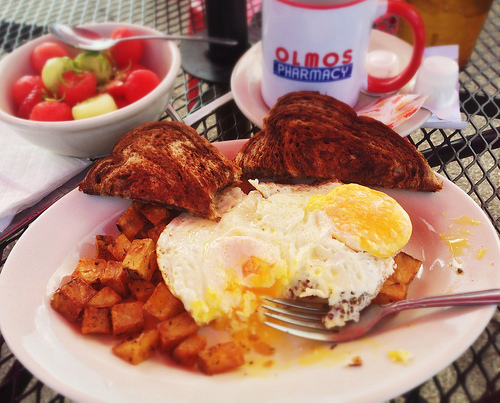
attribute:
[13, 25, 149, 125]
salad — fresh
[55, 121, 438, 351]
breakfast — toast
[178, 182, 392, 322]
eggs — sunny side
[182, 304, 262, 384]
potatoes — diced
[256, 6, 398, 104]
beverage — warm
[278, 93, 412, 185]
toast — crispy, brown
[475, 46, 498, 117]
table — outdoors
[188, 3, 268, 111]
chair — pink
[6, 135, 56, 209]
napkin — quilted, white, paper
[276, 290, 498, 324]
fork — small, silver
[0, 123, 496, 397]
plate — white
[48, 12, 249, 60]
spoon — silver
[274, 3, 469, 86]
cup — red, white